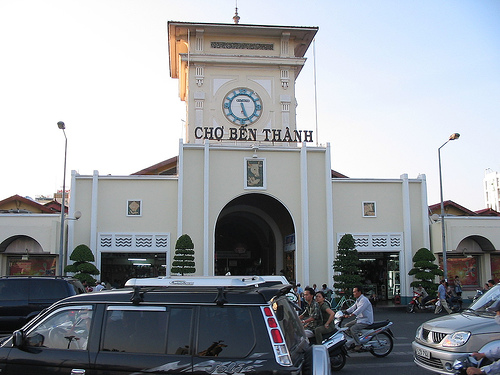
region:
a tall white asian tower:
[163, 3, 336, 293]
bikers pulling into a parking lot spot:
[296, 282, 399, 357]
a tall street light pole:
[47, 113, 77, 274]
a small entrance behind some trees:
[330, 226, 441, 309]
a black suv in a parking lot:
[0, 273, 347, 373]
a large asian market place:
[2, 13, 497, 295]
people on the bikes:
[297, 289, 379, 365]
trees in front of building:
[328, 242, 435, 309]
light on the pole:
[435, 127, 459, 309]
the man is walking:
[434, 282, 456, 311]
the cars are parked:
[2, 290, 312, 372]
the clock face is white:
[226, 91, 258, 121]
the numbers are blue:
[226, 91, 249, 96]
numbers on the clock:
[225, 97, 263, 125]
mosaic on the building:
[232, 157, 287, 189]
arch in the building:
[203, 192, 303, 288]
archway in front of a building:
[206, 185, 303, 291]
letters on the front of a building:
[194, 123, 316, 145]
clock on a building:
[221, 83, 266, 129]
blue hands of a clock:
[237, 99, 248, 120]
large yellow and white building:
[3, 20, 499, 304]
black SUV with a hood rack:
[5, 272, 321, 372]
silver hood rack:
[121, 267, 286, 303]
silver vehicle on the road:
[409, 276, 499, 371]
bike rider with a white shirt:
[345, 283, 377, 352]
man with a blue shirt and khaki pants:
[433, 278, 453, 318]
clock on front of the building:
[220, 85, 262, 125]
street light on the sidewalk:
[437, 131, 462, 286]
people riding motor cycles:
[295, 285, 395, 365]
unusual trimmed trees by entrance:
[330, 230, 440, 305]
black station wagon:
[0, 280, 310, 370]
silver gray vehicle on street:
[407, 280, 497, 371]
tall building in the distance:
[481, 165, 496, 210]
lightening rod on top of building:
[231, 0, 237, 20]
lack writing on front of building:
[191, 125, 311, 140]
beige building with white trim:
[0, 20, 495, 301]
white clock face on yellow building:
[222, 92, 261, 126]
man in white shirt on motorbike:
[324, 280, 396, 357]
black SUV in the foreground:
[3, 273, 332, 371]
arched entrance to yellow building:
[211, 193, 298, 275]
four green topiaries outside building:
[63, 223, 452, 292]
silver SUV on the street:
[393, 279, 498, 373]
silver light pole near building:
[52, 117, 73, 283]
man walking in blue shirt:
[434, 275, 457, 313]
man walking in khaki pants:
[432, 273, 457, 318]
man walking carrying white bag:
[428, 275, 457, 312]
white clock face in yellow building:
[221, 85, 269, 125]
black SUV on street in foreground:
[2, 280, 322, 371]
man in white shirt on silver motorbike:
[328, 284, 398, 356]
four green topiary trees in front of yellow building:
[62, 214, 444, 286]